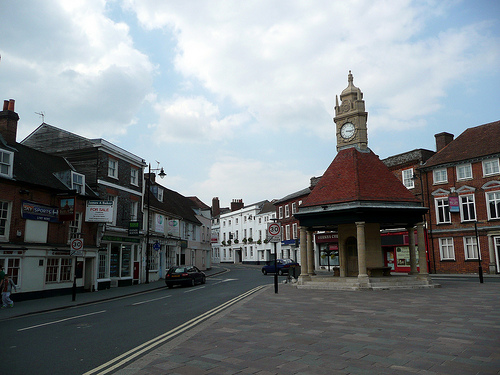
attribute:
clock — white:
[335, 120, 360, 146]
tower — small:
[313, 62, 387, 152]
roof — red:
[311, 153, 408, 200]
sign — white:
[266, 219, 290, 245]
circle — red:
[269, 223, 280, 236]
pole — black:
[272, 245, 288, 294]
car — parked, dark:
[159, 262, 218, 287]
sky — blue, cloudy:
[44, 13, 488, 126]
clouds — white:
[187, 27, 352, 80]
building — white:
[227, 196, 278, 268]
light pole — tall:
[144, 162, 169, 294]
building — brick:
[7, 114, 99, 310]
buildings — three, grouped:
[49, 139, 272, 278]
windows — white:
[105, 161, 139, 185]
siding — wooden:
[364, 230, 384, 272]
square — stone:
[239, 292, 423, 375]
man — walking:
[3, 270, 20, 314]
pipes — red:
[1, 94, 17, 110]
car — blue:
[256, 246, 292, 272]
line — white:
[23, 297, 174, 322]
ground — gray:
[73, 319, 322, 364]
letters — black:
[271, 235, 283, 244]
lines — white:
[30, 288, 178, 317]